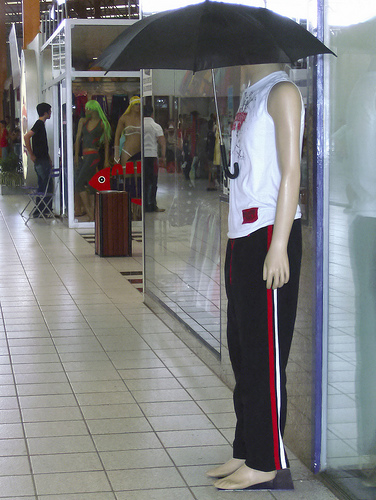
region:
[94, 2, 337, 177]
A black open umbrella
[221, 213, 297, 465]
A pair of striped pants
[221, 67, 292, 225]
A white shirt on a display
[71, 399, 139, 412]
Single piece of floor tile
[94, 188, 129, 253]
A fountain in a mall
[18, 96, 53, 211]
A man looking at clothes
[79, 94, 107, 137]
A green wig on a dsplay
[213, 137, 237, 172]
Black handle on an umbrella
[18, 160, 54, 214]
A purple folding chair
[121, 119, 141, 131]
A see through bra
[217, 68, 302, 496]
mannequin's head is missing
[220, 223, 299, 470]
black pants with red and white stripes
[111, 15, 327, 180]
black umbrella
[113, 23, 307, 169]
black umbrella floating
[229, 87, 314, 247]
white shirt with no sleeves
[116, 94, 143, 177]
mannequin wearing two piece bikini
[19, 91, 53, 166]
man wearing black shirt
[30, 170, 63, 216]
blue chair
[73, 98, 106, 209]
mannequin wearing gray clothing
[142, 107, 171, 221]
reflection of man wearing white shirt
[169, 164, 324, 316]
this is a statue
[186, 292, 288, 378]
this is a pair of pants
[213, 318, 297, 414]
the pants are black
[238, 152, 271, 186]
this is a white shirt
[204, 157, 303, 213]
the shirt is short sleeved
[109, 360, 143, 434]
this is a tile floor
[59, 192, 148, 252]
this is a trash can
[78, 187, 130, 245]
the trash is wooden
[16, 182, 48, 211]
this is a chair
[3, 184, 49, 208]
the chair is plastic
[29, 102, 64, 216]
man in front of store window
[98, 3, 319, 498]
mannequin in window with umbrella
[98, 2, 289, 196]
umbrella near the mannequin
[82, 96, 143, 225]
mannequins in the window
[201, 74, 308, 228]
shirt on the mannequin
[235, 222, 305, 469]
pants on the mannequin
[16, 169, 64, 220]
chair outside the store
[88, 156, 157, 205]
graphics on the window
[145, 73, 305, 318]
glass to front of store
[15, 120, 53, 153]
shirt on the man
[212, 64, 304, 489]
mannequin wearing black striped track pants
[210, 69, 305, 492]
mannequin wearing white tank top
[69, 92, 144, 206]
pair of manequins in skimpy clothing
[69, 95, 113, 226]
mannequin with green hair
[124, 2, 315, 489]
mannequin with no head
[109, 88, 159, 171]
mannequin with yellow hair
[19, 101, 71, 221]
man observing two mannequins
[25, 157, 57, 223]
metal chair standing next to man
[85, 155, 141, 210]
red fish decal on window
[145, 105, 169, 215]
man's reflection in window